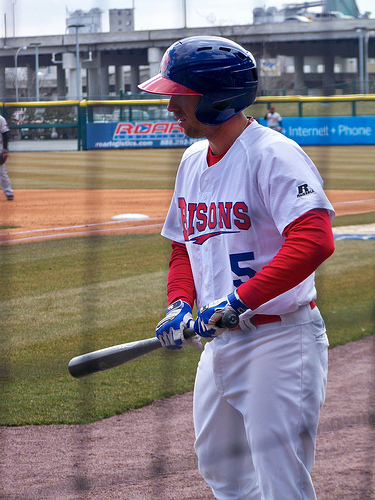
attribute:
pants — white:
[191, 323, 336, 499]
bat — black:
[71, 311, 247, 383]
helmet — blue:
[133, 34, 260, 129]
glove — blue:
[156, 302, 197, 347]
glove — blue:
[186, 297, 242, 344]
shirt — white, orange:
[160, 129, 340, 315]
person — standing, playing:
[136, 30, 339, 496]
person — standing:
[2, 110, 11, 212]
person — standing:
[263, 101, 283, 140]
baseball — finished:
[2, 2, 371, 499]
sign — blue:
[88, 120, 373, 156]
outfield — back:
[1, 3, 369, 465]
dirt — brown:
[3, 184, 374, 247]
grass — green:
[4, 210, 374, 423]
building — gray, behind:
[106, 8, 141, 35]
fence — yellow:
[4, 93, 374, 110]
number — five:
[226, 250, 257, 290]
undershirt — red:
[164, 133, 335, 313]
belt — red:
[205, 301, 325, 327]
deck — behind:
[5, 21, 370, 116]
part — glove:
[0, 152, 12, 163]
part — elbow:
[1, 117, 17, 151]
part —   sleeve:
[0, 115, 10, 132]